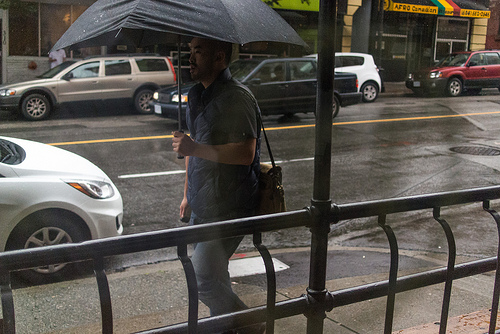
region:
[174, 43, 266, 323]
Man holding black umbrella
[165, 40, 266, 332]
Man wearing brown suitcase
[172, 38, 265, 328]
Man walking past white car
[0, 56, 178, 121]
Champagne colored car is parked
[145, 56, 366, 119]
Black car has lights on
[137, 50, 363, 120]
Black car passing by champagne colored car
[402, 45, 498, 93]
Red car behind white car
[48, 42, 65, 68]
Person by champagne colored car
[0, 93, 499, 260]
Street is wet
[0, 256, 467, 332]
Sidewalk is wet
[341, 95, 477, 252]
The pavement is wet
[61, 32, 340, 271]
The man is holding an umbrella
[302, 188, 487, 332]
The fence is made of metal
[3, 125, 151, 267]
The car is white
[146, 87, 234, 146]
The car has its lights on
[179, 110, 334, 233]
The man has a short sleeve shirt on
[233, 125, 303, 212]
The man has a bag with him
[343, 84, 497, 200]
The road has lines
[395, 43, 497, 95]
The vehicle is red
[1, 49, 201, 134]
The car is parked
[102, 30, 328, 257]
a man wearing a bag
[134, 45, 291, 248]
a man wearing a tshirt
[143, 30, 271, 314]
a man wearing pants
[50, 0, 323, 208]
a man holding a black umbrella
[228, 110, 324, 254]
a laptop bag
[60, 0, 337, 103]
a black umbrella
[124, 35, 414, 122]
a black car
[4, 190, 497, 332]
a black metal fence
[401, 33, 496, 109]
a red vehicle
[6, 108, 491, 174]
yellow lines on a road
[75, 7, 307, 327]
man walking in the rain with an umbrella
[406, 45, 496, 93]
parked red car on the street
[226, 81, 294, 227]
leather over the shoulder satchel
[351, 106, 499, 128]
solid yellow line on the road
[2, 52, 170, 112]
tan SUV parked at the curb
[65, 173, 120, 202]
one headlight on a vehicle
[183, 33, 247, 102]
Asian man holding an umbrella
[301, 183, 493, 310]
metal fencing along the sidewalk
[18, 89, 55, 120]
wheel of a parked vehicle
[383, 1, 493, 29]
colorful awning of a store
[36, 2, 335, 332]
a man holding an umbrella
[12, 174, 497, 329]
black metal railing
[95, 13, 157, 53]
broken part of an umbrella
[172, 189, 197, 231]
man holding phone in right hand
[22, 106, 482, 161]
yellow line going down middle of road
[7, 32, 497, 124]
vehicles parked on side of the street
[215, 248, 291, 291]
a silver metal lid near curb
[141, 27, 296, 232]
man is carrying brown book bag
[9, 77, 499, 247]
street is wet from rain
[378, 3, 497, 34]
yellow, green, and red banner above store